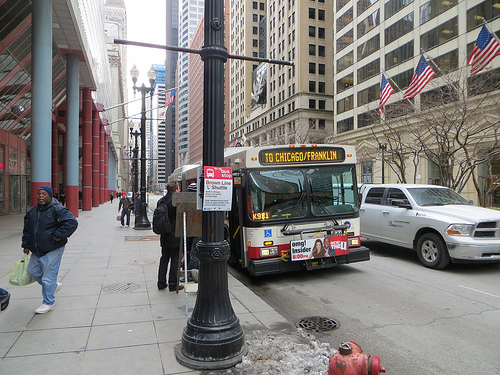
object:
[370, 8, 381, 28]
window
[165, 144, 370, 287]
bus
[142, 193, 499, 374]
street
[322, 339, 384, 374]
hydrant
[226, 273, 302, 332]
curb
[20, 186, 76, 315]
male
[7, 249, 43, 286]
bag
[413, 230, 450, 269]
tire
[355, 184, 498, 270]
vehicle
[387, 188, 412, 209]
window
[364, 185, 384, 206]
window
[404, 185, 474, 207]
window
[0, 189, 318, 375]
sidewalk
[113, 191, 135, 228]
person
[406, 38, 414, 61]
window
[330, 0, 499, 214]
building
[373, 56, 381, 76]
window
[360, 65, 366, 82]
window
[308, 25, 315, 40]
window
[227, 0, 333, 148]
building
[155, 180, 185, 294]
people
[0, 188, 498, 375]
outdoors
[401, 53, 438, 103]
flag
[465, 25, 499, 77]
flag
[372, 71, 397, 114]
flag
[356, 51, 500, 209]
tree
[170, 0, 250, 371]
pole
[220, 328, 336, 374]
snow